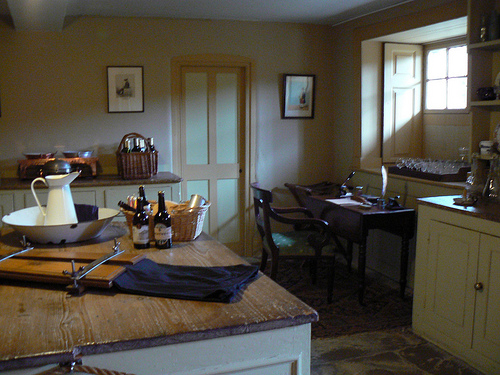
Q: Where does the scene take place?
A: In a house.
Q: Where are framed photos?
A: On the wall.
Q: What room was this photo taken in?
A: The kitchen.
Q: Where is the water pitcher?
A: On the counter.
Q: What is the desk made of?
A: Wood.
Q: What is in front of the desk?
A: A window.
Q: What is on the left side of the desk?
A: A door.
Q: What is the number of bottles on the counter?
A: Two.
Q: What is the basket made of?
A: Wicker.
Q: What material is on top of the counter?
A: Wood.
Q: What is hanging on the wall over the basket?
A: A picture.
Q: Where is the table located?
A: In the kitchen.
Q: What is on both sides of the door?
A: A painting.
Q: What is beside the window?
A: A desk.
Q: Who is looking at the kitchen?
A: The photographer.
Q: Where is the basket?
A: To the left of the door.